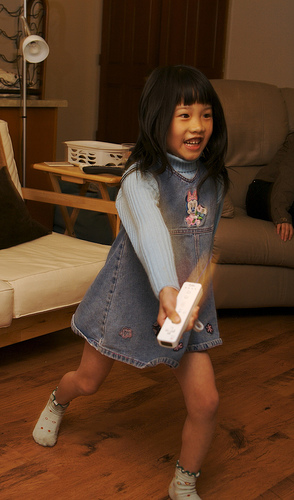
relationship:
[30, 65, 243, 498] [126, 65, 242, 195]
girl with hair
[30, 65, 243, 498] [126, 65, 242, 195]
girl with black hair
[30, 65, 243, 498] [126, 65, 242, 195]
girl with straight hair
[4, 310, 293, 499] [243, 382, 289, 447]
floor made of wood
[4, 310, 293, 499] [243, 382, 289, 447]
floor of wood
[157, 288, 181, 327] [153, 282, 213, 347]
hand holding remote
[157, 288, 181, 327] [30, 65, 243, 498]
hand of person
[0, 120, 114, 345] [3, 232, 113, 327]
seat of leather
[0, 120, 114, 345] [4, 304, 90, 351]
seat has wood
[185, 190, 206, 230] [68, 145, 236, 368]
mouse on dress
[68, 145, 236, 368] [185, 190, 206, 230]
dress has mouse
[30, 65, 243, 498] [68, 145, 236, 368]
girl wearing dress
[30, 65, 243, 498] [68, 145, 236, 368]
girl wearing jean dress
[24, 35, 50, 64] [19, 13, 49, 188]
light of lamp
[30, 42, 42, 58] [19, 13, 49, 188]
bulb of lamp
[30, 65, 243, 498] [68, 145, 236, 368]
girl blue dress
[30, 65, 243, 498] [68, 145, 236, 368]
girl denim dress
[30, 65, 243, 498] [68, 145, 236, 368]
girl wearing blue dress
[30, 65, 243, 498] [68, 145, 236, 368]
girl wearing denim dress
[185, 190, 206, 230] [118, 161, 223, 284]
mouse on clothing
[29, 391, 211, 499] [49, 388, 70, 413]
socks with green trim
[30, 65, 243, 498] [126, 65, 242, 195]
girl long hair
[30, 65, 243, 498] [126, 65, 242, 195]
girl black hair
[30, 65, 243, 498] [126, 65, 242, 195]
girl straight black hair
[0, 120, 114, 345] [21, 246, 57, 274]
chair cushion white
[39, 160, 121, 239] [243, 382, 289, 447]
table made of wood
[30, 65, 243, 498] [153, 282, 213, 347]
girl holding wii remote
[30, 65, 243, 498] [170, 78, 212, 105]
girl has bangs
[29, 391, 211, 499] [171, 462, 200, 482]
socks has ruffles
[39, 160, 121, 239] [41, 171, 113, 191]
table can fold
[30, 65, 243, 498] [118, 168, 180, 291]
girl has girl sweater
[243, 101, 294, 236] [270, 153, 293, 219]
person on sofa has arm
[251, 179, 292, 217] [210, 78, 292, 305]
blanket on sofa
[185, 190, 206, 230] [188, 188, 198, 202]
mouse has bow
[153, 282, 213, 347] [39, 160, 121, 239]
remote on table